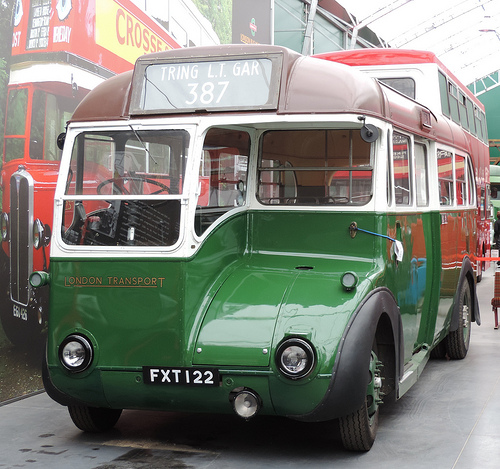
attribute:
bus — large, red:
[1, 0, 211, 346]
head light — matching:
[272, 335, 323, 380]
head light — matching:
[48, 327, 100, 378]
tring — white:
[155, 61, 203, 85]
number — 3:
[185, 82, 198, 105]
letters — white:
[142, 360, 220, 391]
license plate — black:
[107, 327, 236, 412]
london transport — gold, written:
[55, 266, 173, 297]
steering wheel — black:
[89, 169, 170, 207]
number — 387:
[182, 79, 237, 109]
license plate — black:
[141, 364, 220, 387]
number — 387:
[176, 78, 228, 118]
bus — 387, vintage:
[21, 39, 491, 454]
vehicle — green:
[30, 43, 497, 450]